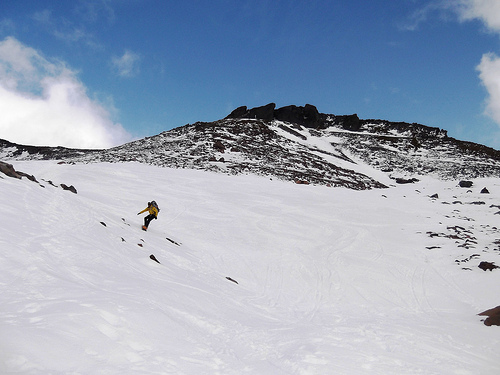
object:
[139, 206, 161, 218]
shirt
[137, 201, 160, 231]
hiker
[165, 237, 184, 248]
black rock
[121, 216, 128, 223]
black rock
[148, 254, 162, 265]
black rock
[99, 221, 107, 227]
black rock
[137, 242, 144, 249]
black rock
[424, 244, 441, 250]
rocks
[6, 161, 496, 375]
snow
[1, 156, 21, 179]
rock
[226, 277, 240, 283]
black rock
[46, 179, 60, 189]
black rock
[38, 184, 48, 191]
black rock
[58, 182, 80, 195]
black rock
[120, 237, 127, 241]
black rock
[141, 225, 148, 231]
snowboard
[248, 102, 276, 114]
rocks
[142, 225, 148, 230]
shoe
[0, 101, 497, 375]
hill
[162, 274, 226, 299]
tracks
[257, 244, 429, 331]
snow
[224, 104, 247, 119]
rocks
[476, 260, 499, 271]
rocks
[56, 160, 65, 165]
rock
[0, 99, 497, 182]
mountain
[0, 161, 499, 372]
hillside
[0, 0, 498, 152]
sky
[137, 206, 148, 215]
outstretched arm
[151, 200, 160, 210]
backpack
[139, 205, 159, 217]
coat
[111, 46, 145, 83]
clouds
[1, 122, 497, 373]
slope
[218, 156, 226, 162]
rock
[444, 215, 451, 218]
rock pieces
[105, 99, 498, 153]
summit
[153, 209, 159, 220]
arm